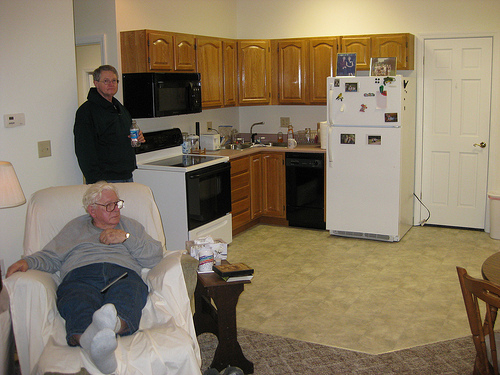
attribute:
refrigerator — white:
[322, 73, 416, 244]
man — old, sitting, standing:
[6, 181, 167, 372]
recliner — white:
[2, 181, 204, 375]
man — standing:
[70, 63, 146, 180]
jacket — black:
[73, 86, 140, 181]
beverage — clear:
[129, 119, 141, 150]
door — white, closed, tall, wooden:
[417, 29, 495, 232]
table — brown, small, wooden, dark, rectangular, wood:
[191, 254, 257, 375]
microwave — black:
[123, 72, 203, 122]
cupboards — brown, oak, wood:
[117, 30, 413, 112]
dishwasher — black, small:
[281, 150, 328, 232]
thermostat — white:
[2, 109, 28, 128]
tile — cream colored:
[227, 217, 498, 356]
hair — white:
[82, 181, 119, 210]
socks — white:
[74, 303, 125, 374]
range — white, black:
[133, 127, 233, 258]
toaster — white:
[201, 130, 222, 154]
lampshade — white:
[0, 158, 28, 213]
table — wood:
[479, 246, 500, 295]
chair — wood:
[456, 263, 499, 374]